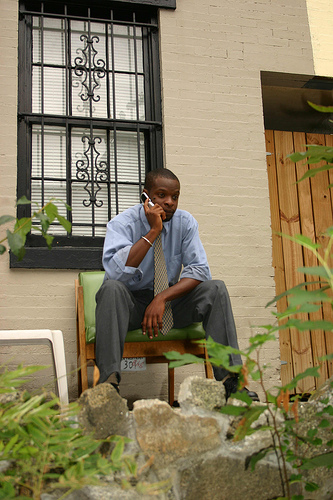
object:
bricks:
[225, 284, 247, 296]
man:
[91, 166, 260, 409]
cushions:
[78, 270, 211, 343]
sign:
[122, 355, 144, 372]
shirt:
[100, 205, 211, 297]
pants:
[93, 276, 244, 388]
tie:
[151, 230, 174, 337]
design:
[151, 230, 174, 337]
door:
[248, 69, 331, 403]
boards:
[266, 128, 333, 400]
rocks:
[131, 394, 221, 456]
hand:
[143, 198, 168, 232]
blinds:
[31, 18, 146, 234]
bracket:
[275, 380, 317, 406]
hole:
[321, 186, 329, 203]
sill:
[4, 232, 105, 271]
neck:
[138, 207, 172, 235]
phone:
[138, 186, 164, 228]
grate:
[18, 0, 167, 243]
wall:
[0, 1, 331, 415]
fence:
[262, 131, 333, 391]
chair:
[75, 272, 215, 402]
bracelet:
[138, 232, 156, 246]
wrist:
[140, 226, 161, 242]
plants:
[161, 330, 316, 498]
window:
[16, 4, 153, 240]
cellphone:
[139, 190, 162, 220]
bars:
[30, 114, 142, 130]